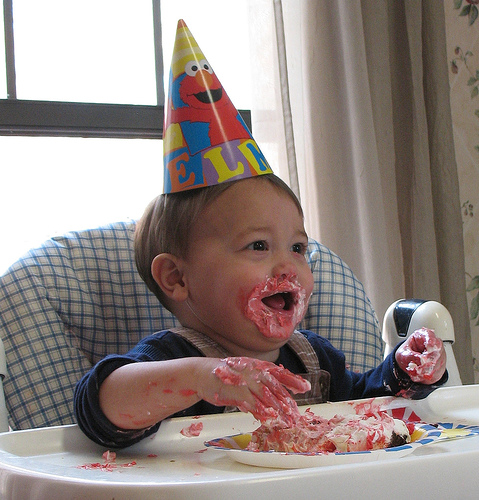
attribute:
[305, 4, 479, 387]
curtain — tan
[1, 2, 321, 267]
window — open, sunlit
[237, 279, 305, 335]
cream — red, white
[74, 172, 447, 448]
child — very happy, male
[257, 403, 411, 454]
cake — sliced, red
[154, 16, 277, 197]
party hat — cone shaped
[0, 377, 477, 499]
table — white, messy, dirty